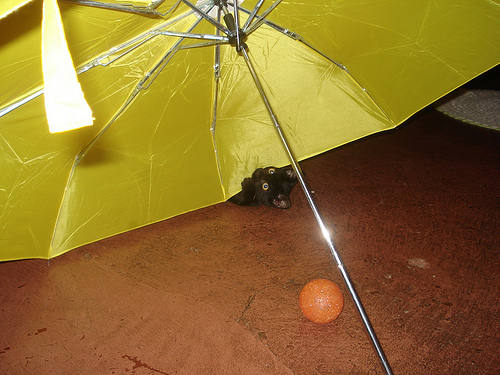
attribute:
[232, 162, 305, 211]
cat — black, kitten, small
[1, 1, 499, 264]
umbrella — yellow, open, fabric, large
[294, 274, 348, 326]
ball — orange, red, small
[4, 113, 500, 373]
ground — cement, clean, brown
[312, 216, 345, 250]
light — reflection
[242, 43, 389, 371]
handle — metal, black, plastic, shiny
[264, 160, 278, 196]
eyes — yellow, green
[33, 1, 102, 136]
object — white, tag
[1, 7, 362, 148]
frame — metal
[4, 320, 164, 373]
spots — dark